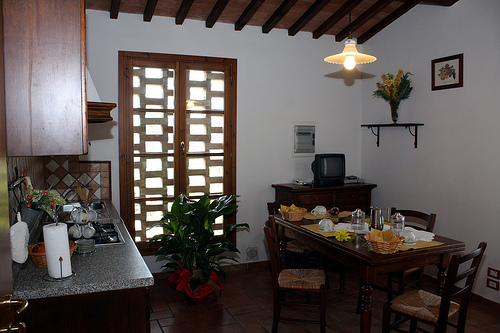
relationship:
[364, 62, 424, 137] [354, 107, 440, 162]
flowers on shelf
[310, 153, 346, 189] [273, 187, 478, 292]
t.v on top of table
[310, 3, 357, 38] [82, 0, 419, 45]
rafter on ceiling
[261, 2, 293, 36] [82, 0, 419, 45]
rafter on ceiling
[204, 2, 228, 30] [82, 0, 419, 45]
rafter on ceiling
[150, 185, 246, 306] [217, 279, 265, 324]
plant on floor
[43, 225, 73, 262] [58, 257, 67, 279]
paper towel on holder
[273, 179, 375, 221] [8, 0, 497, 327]
bureau in room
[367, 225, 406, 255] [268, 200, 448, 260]
basket on table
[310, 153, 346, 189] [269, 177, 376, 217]
t.v on stand